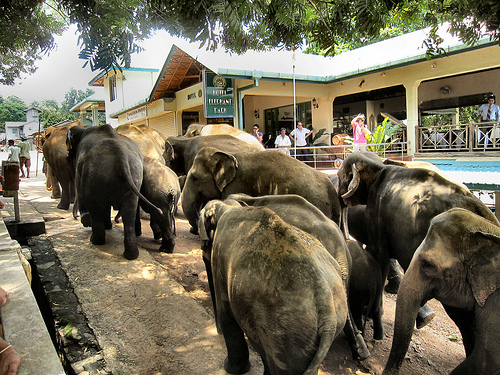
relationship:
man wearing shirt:
[285, 122, 314, 168] [290, 127, 311, 144]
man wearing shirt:
[275, 127, 292, 151] [273, 134, 291, 146]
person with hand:
[348, 112, 369, 154] [361, 121, 368, 131]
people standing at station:
[230, 116, 420, 189] [51, 7, 498, 177]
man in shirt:
[477, 93, 500, 149] [475, 101, 498, 121]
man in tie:
[477, 93, 500, 149] [485, 102, 492, 122]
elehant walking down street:
[197, 198, 349, 375] [20, 150, 463, 373]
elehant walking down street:
[382, 206, 500, 375] [20, 150, 463, 373]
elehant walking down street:
[337, 151, 500, 329] [20, 150, 463, 373]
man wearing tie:
[473, 93, 498, 128] [486, 105, 492, 117]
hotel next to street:
[118, 30, 498, 154] [29, 235, 212, 364]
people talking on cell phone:
[251, 124, 264, 143] [251, 124, 261, 132]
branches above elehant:
[2, 2, 495, 58] [197, 198, 349, 375]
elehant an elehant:
[197, 198, 349, 375] [382, 206, 500, 375]